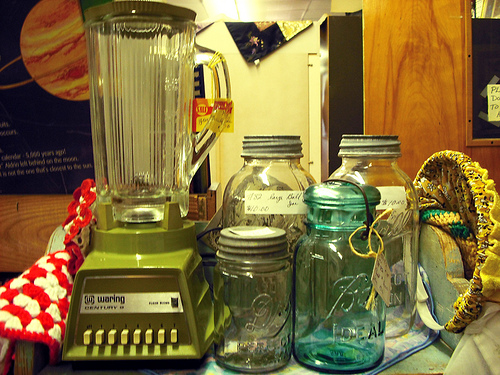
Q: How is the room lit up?
A: A light from the ceiling.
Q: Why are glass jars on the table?
A: For storage.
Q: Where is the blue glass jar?
A: On the table.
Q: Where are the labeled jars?
A: Behind the small jars.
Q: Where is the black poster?
A: Behind the blender.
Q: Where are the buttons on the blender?
A: On the bottom.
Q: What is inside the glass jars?
A: Nothing.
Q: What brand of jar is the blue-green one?
A: Ball.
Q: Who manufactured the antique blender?
A: Waring.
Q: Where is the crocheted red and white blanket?
A: Next to the blender.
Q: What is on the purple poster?
A: Planet.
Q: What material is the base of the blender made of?
A: Plastic.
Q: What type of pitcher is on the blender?
A: Glass.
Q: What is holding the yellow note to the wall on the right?
A: Scotch tape.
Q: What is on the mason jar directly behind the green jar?
A: Price label.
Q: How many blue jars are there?
A: One.